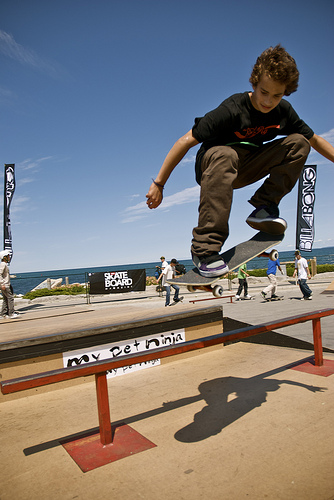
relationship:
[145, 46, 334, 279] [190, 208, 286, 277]
boy has shoes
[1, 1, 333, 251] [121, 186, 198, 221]
sky has clouds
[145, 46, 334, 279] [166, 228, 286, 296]
boy rides skateboard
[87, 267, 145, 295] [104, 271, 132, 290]
banner has lettering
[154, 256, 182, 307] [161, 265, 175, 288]
boy wears shirt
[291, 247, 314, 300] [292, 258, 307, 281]
boy wears t-shirt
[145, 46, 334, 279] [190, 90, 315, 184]
boy wears black tshirt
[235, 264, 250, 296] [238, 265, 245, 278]
boy wears shirt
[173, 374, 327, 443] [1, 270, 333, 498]
reflection on ground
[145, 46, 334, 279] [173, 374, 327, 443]
boy has reflection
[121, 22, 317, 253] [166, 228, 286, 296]
boy on skateboard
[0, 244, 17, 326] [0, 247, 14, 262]
kid wearing helmet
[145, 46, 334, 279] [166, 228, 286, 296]
boy on skateboard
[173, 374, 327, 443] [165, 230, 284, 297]
reflection of skatboard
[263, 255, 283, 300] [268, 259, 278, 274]
skateboarder has blue shirt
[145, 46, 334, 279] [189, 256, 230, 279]
boy has shoe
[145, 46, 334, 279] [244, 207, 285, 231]
boy has shoe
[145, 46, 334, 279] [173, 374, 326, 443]
boy has a reflection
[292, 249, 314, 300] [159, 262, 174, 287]
boy wearing a shirt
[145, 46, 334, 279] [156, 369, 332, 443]
boy has a shadow